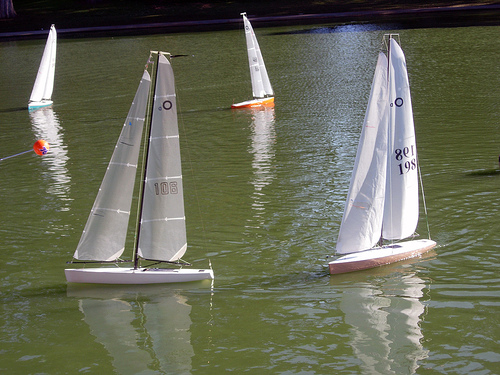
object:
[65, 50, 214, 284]
toy boat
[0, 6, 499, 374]
water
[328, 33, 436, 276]
toy boat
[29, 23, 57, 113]
toy boat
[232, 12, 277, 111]
toy boat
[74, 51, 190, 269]
sail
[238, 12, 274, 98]
sail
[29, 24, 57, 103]
sail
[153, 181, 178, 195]
numbers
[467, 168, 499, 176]
shadow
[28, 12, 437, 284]
toy boats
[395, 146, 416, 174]
numbers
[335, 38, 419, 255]
sail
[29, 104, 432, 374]
reflection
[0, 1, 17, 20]
trunk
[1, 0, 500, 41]
ledge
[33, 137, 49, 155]
fishing bobber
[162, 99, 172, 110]
circle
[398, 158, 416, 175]
198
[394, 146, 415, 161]
numbers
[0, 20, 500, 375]
sunlight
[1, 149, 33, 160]
string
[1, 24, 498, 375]
ripples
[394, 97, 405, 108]
circle